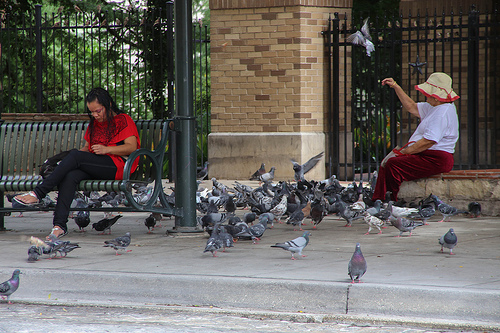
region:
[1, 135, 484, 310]
flock of birds on sidewalk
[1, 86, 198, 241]
woman sitting on bench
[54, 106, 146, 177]
woman wearing red shirt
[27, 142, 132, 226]
woman wearing black pants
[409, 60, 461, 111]
woman wearing tan hat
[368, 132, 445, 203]
woman wearing maroon bottoms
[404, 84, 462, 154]
woman wearing white shirt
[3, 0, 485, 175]
iron fence behind woman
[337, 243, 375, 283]
grey and red bird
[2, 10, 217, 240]
green bench and pole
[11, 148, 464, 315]
several pigeons are on the sidewalk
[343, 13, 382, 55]
this pigeon is flying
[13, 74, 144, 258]
the woman sits on a park bench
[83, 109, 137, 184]
the woman wears a red shirt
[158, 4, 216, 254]
a pole is on the sidewalk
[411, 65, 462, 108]
this woman wears a hat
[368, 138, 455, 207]
the woman is wearing red pants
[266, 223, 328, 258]
the bird is grey in color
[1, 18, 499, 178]
a black fence is in the background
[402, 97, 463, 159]
the woman is wearing a white t-shirt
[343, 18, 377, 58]
pigeon flying in the air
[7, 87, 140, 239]
woman sitting on a bench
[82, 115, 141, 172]
woman's shirt is red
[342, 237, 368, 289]
pigeon facing the curb's edge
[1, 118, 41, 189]
bench is green and metal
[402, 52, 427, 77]
black star on iron fence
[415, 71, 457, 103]
woman's hat is tan and red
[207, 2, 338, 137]
part on the fence is made of bricks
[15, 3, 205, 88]
trees are behind the fence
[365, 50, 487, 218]
this is a woman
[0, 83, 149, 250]
this is a woman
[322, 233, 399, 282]
this is a bird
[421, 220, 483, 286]
this is a bird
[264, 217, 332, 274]
this is a bird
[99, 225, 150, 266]
this is a bird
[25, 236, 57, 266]
this is a bird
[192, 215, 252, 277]
this is a bird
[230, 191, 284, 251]
this is a bird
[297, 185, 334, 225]
this is a bird